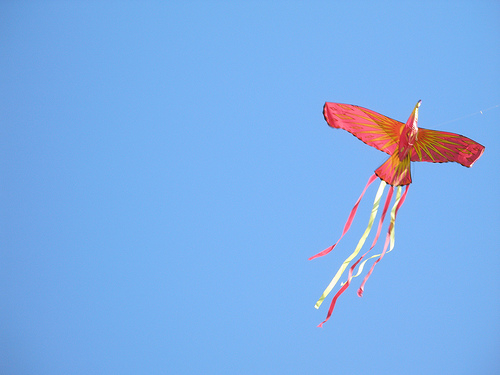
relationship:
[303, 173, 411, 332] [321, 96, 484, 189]
ribbons on kite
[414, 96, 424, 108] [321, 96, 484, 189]
point of kite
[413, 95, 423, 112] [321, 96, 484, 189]
end of kite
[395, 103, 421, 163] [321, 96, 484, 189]
body of kite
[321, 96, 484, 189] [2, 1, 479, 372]
kite in sky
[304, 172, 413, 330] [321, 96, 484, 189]
tail of a kite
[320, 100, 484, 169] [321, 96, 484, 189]
wings of a kite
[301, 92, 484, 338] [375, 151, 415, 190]
kite has tail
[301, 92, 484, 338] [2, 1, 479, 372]
kite flying in sky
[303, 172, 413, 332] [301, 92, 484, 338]
streamers on kite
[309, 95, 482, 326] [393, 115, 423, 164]
kite has body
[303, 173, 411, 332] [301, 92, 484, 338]
ribbons on kite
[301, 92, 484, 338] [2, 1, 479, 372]
kite in sky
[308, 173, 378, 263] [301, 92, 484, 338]
string on kite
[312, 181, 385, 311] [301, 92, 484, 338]
string on kite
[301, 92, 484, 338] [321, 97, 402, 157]
kite has wing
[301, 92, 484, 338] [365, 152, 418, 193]
kite has tail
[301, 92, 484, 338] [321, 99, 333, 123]
kite has tip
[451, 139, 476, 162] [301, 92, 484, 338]
design on kite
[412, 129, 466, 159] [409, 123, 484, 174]
design on wing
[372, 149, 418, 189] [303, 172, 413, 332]
tail with streamers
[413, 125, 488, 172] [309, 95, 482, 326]
wing on kite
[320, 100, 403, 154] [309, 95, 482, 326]
wing on kite